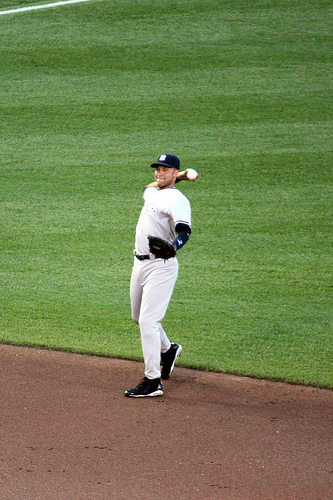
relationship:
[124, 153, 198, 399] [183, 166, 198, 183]
man holding ball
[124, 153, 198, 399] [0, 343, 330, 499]
man on dirt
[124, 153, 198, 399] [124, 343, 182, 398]
man wearing cleats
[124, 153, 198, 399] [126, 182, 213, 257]
man wearing jersey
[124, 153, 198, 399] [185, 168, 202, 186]
man throwing ball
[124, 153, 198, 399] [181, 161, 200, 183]
man throwing ball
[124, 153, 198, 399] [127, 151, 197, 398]
man in uniform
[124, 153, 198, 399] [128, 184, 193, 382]
man in uniform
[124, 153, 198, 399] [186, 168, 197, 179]
man holding ball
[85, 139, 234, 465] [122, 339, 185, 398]
man wearing cleats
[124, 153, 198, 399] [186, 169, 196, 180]
man throwing baseball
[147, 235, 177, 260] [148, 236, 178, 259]
baseball glove in hand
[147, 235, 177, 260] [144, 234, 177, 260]
baseball glove in hand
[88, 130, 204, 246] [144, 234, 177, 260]
baseball glove in hand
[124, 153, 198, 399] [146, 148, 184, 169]
man in hat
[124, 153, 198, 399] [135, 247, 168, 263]
man wearing a belt